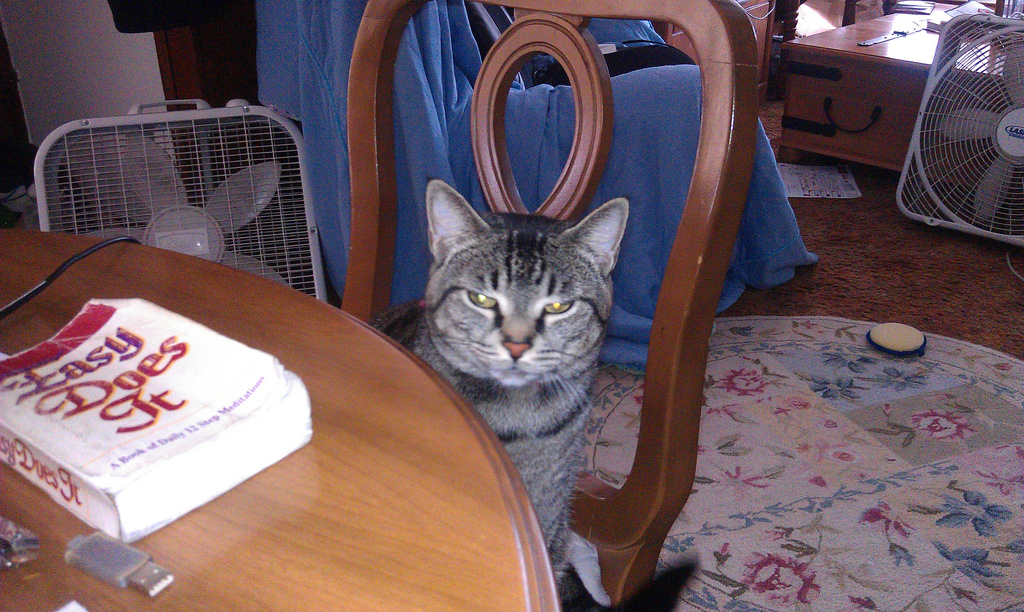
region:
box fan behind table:
[22, 89, 327, 295]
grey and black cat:
[416, 174, 616, 583]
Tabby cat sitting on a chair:
[372, 7, 715, 600]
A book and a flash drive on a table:
[11, 291, 413, 602]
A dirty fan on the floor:
[45, 112, 325, 300]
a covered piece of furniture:
[299, 0, 781, 215]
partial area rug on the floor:
[697, 351, 1015, 607]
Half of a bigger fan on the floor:
[883, 1, 1016, 243]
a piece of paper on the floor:
[773, 159, 850, 199]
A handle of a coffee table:
[785, 26, 906, 160]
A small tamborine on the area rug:
[866, 311, 930, 362]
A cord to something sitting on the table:
[0, 236, 124, 307]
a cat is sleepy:
[391, 218, 639, 422]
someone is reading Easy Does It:
[0, 288, 352, 551]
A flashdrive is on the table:
[41, 534, 188, 607]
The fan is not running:
[859, 1, 1018, 271]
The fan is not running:
[28, 67, 329, 330]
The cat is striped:
[370, 189, 636, 598]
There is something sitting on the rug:
[844, 290, 999, 370]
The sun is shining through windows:
[739, 1, 1008, 147]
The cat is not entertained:
[405, 165, 643, 539]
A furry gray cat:
[410, 170, 636, 567]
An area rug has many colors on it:
[735, 319, 1001, 599]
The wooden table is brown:
[310, 460, 469, 590]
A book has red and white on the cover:
[5, 309, 301, 518]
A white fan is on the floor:
[16, 104, 356, 260]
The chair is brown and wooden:
[322, 8, 734, 579]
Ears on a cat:
[414, 162, 637, 277]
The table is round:
[3, 201, 564, 572]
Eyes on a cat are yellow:
[458, 267, 589, 328]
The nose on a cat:
[495, 333, 537, 371]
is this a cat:
[407, 168, 639, 432]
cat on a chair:
[354, 0, 791, 485]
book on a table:
[10, 351, 311, 478]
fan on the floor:
[897, 36, 1015, 270]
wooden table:
[247, 495, 312, 606]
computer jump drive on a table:
[68, 520, 158, 596]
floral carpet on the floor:
[761, 397, 976, 574]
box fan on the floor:
[76, 95, 304, 244]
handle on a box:
[799, 64, 898, 159]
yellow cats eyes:
[438, 263, 588, 324]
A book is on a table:
[21, 285, 311, 534]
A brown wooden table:
[329, 392, 471, 559]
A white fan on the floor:
[901, 10, 1021, 273]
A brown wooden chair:
[325, 10, 787, 544]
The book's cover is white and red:
[11, 300, 262, 547]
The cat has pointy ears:
[411, 162, 637, 284]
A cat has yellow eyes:
[448, 269, 607, 350]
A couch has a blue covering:
[288, 12, 824, 357]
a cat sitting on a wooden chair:
[351, 0, 744, 610]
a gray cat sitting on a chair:
[369, 176, 633, 606]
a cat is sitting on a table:
[16, 138, 893, 609]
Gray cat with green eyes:
[432, 178, 641, 556]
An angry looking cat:
[406, 174, 632, 526]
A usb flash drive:
[59, 520, 170, 593]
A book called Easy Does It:
[0, 295, 307, 520]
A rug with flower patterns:
[614, 308, 1010, 599]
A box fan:
[892, 7, 1013, 227]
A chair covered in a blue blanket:
[256, 0, 806, 295]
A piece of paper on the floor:
[770, 157, 854, 192]